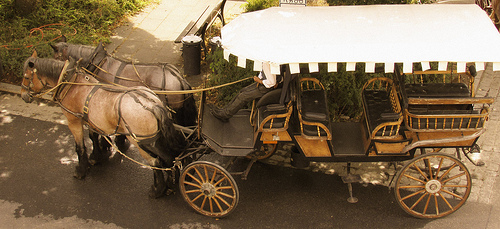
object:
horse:
[18, 50, 185, 197]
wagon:
[178, 2, 499, 222]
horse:
[48, 35, 201, 132]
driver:
[206, 55, 283, 121]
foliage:
[3, 3, 90, 80]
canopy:
[219, 4, 500, 74]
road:
[0, 89, 499, 227]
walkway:
[396, 50, 499, 207]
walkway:
[99, 0, 243, 144]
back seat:
[400, 70, 474, 104]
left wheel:
[176, 160, 241, 218]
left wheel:
[391, 151, 473, 222]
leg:
[70, 120, 90, 181]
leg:
[88, 127, 105, 167]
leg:
[151, 155, 168, 202]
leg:
[163, 164, 177, 196]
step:
[347, 185, 359, 205]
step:
[337, 162, 364, 183]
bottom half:
[212, 81, 273, 121]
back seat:
[402, 104, 489, 135]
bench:
[174, 0, 227, 45]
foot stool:
[465, 144, 487, 167]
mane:
[29, 55, 77, 80]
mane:
[57, 42, 102, 63]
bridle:
[19, 52, 49, 98]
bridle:
[55, 44, 69, 61]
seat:
[363, 87, 396, 135]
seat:
[300, 89, 328, 135]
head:
[20, 49, 60, 103]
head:
[48, 33, 83, 61]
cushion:
[303, 88, 329, 121]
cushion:
[362, 88, 396, 128]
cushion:
[402, 79, 471, 99]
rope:
[68, 75, 259, 95]